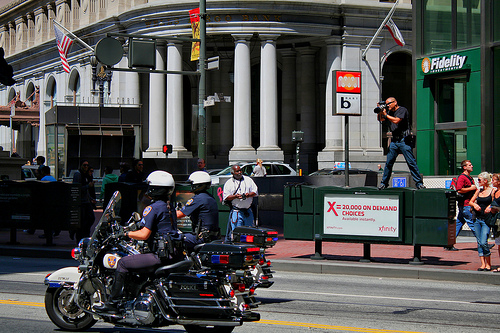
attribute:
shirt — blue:
[142, 201, 179, 243]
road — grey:
[5, 260, 497, 331]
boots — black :
[90, 273, 135, 318]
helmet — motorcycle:
[147, 171, 176, 198]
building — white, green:
[11, 24, 385, 184]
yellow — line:
[276, 312, 358, 331]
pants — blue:
[123, 253, 160, 270]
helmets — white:
[135, 157, 226, 204]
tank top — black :
[469, 187, 497, 217]